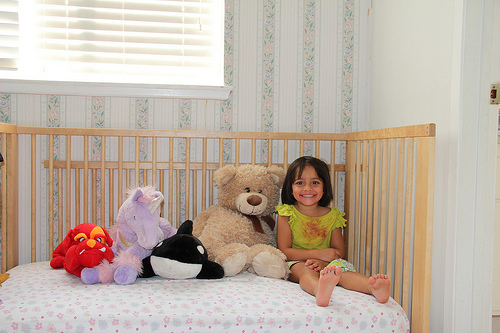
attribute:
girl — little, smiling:
[277, 157, 390, 308]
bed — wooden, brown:
[0, 122, 434, 332]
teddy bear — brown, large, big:
[191, 164, 286, 279]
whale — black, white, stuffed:
[136, 220, 223, 279]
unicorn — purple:
[81, 185, 178, 284]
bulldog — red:
[50, 223, 114, 277]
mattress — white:
[2, 261, 410, 333]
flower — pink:
[164, 318, 168, 322]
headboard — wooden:
[16, 126, 350, 265]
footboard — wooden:
[44, 161, 366, 261]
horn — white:
[150, 195, 164, 212]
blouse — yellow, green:
[276, 204, 347, 250]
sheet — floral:
[1, 261, 408, 333]